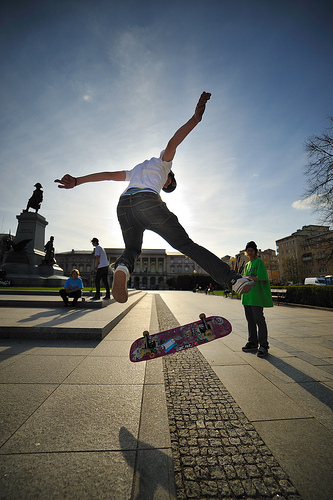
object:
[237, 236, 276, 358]
boy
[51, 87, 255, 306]
boy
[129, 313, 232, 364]
skateboard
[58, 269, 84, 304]
boy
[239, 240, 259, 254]
cap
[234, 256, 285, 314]
shirt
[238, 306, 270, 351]
pants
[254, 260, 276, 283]
sleeve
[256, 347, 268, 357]
shoes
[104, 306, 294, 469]
air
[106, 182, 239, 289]
pants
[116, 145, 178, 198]
shirt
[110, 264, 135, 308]
shoe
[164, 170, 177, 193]
cap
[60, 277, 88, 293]
shirt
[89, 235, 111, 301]
boy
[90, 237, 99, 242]
hat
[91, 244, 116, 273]
shirt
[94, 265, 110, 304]
pants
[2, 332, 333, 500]
ground